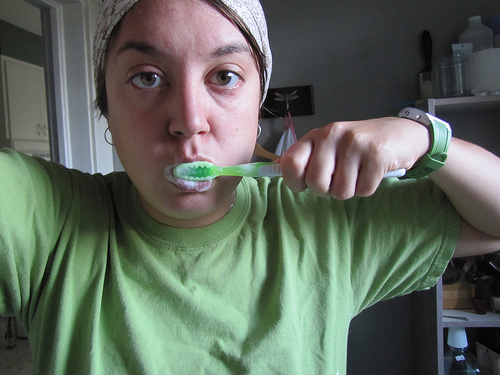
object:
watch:
[381, 103, 455, 204]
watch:
[3, 2, 498, 366]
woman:
[1, 0, 498, 372]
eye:
[123, 62, 168, 89]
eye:
[204, 61, 245, 93]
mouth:
[165, 156, 217, 192]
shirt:
[2, 153, 449, 371]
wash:
[442, 318, 466, 372]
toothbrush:
[178, 161, 408, 181]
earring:
[103, 126, 116, 146]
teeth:
[174, 160, 283, 179]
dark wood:
[292, 101, 318, 116]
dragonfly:
[272, 86, 301, 108]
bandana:
[205, 6, 277, 48]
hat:
[92, 0, 273, 101]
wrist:
[397, 108, 455, 181]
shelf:
[441, 307, 484, 370]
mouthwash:
[444, 329, 482, 371]